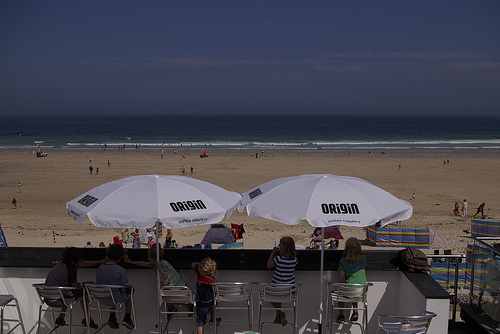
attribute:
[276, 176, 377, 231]
umbrella — white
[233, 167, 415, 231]
umbrella — white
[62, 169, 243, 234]
umbrella — white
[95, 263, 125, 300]
shirt — blue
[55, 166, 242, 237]
umbrella — white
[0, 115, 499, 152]
sea water — blue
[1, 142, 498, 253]
beach — large, sandy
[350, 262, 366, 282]
shirt — green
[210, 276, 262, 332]
chair — small, metal